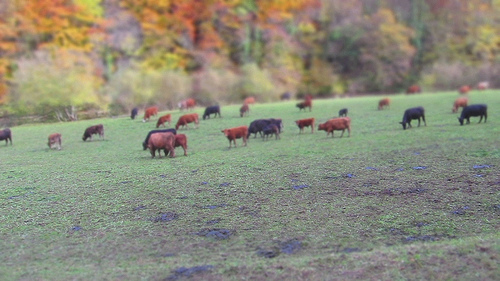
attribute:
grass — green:
[3, 87, 498, 279]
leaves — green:
[397, 24, 431, 71]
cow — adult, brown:
[146, 130, 186, 162]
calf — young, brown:
[324, 109, 354, 139]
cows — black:
[60, 45, 440, 190]